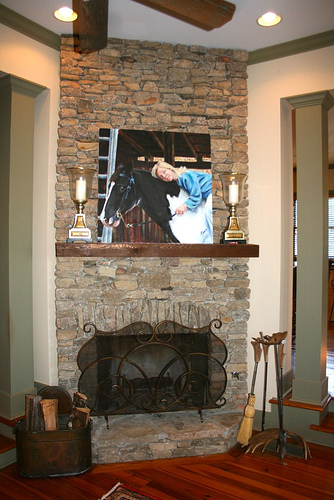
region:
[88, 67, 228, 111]
Gray bricks on a fireplace.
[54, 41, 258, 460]
A fireplace in the room.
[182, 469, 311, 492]
Brown wood on the floor.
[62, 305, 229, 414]
A fireplace cover.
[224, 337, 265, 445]
Little broom for sweeping the fireplace.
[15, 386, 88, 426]
Logs for the fire.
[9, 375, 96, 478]
Container for holding fire logs.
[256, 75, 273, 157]
Part of the wall is white.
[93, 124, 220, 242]
Picture of a woman on a horse.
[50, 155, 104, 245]
A candle holder on the mantle of the fireplace.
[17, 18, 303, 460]
corner with fireplace and large picture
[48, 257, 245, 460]
stone fireplace covered with curlicue screen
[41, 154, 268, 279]
wood mantle with identical candleholders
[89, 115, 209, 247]
woman resting head on neck of horse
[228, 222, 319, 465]
fireplace tools and antler in front of column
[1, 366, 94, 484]
old metal basket holding pieces of firewood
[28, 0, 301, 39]
shining light fixtures in ceiling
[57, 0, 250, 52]
brown blades of ceiling fan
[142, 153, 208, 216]
blonde woman in draped blue garment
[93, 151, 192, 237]
black and white horse in front of stable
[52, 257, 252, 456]
grey stone fireplace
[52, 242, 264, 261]
wooden beam acting as a mantle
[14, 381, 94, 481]
copper tub holding fire wood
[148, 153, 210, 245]
girl wearing blue top with blonde hair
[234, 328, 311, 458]
fireplace broom and andirons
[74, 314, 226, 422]
an ornate firescreen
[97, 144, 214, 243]
girl on black and white horse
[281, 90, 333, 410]
green column next to fireplace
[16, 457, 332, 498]
red stained hardwood floors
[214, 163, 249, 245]
white candle in candleholder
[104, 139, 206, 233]
a picture of a blonde woman with a horse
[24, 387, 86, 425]
several sticks of tree wood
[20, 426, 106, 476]
a brass wood container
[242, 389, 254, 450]
a brown chimney sweeper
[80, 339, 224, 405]
a black fireplace screen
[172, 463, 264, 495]
red wood floor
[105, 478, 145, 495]
the corner of an ornate rug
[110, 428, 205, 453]
the rock ledge of a fireplace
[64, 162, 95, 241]
a large candle holder to the left of a picture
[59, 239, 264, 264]
a brown wooden fireplace mantle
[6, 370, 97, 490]
container with logs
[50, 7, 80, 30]
light on left side of ceiling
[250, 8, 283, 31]
light on right side of ceiling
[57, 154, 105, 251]
candle is white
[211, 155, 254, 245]
candle is on top of a chimney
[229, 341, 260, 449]
a broom next to chimney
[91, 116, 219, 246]
picture over the chimney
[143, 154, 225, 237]
lady over a horse in a photo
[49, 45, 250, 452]
chimney is made of stones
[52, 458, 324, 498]
floor of the room is wood